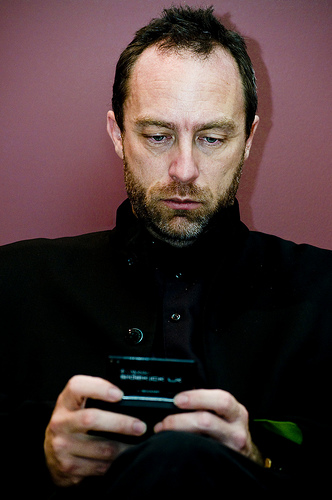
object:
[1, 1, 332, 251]
wall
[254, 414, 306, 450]
lining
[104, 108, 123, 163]
ear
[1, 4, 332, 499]
man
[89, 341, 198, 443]
device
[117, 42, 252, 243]
face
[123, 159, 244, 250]
beard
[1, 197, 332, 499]
jacket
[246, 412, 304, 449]
pocket liner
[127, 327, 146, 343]
light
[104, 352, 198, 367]
light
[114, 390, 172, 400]
light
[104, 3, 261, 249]
head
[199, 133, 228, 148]
eye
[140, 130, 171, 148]
eye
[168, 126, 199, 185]
nose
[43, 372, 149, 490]
hand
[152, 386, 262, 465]
hand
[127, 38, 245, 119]
forehead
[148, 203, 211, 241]
chin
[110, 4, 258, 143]
hair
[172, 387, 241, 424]
finger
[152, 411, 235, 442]
finger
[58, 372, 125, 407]
finger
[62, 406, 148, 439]
finger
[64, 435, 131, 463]
finger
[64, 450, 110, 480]
finger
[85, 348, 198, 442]
phone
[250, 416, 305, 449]
fabric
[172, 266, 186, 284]
button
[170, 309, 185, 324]
button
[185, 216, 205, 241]
patch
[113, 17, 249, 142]
hairline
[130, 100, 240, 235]
expression